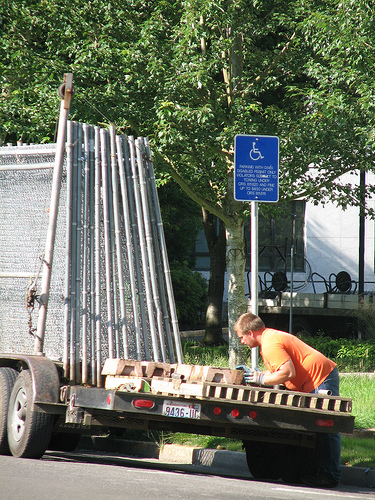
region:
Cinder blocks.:
[114, 331, 198, 399]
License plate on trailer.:
[156, 387, 248, 426]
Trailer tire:
[9, 375, 64, 454]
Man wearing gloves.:
[223, 293, 370, 413]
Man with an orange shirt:
[223, 290, 365, 413]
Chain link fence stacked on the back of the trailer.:
[40, 276, 150, 325]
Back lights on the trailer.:
[97, 380, 168, 428]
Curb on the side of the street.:
[184, 444, 239, 475]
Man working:
[218, 278, 348, 430]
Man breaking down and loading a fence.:
[159, 274, 311, 414]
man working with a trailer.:
[19, 55, 354, 450]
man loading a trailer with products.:
[36, 257, 344, 455]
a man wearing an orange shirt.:
[222, 297, 355, 464]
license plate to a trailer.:
[141, 394, 221, 442]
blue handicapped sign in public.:
[226, 120, 287, 224]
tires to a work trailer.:
[1, 361, 61, 468]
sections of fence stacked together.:
[6, 73, 183, 360]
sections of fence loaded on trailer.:
[0, 180, 353, 418]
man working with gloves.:
[235, 310, 296, 389]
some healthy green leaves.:
[99, 21, 331, 119]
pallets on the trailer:
[76, 361, 351, 430]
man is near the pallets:
[103, 369, 351, 415]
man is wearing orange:
[258, 328, 338, 390]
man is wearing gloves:
[235, 364, 269, 388]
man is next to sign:
[228, 129, 346, 411]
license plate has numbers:
[160, 399, 201, 418]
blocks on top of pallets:
[105, 356, 243, 394]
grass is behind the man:
[182, 335, 374, 463]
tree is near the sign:
[0, 1, 374, 307]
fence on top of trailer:
[1, 73, 189, 385]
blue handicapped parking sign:
[226, 125, 286, 215]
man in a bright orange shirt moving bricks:
[231, 308, 348, 396]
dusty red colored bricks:
[100, 354, 244, 388]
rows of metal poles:
[57, 114, 187, 359]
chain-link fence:
[0, 139, 64, 358]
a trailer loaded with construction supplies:
[0, 350, 353, 486]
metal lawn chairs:
[261, 262, 357, 298]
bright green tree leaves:
[0, 0, 374, 132]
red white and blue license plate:
[161, 399, 202, 423]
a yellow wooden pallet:
[150, 375, 357, 417]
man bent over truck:
[234, 308, 352, 493]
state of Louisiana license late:
[159, 392, 206, 427]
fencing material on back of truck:
[4, 110, 188, 399]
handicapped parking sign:
[225, 123, 278, 405]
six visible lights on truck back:
[77, 392, 372, 439]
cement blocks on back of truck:
[101, 349, 360, 422]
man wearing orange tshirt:
[226, 310, 334, 390]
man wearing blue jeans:
[289, 353, 351, 489]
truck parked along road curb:
[4, 364, 321, 494]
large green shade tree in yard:
[23, 23, 353, 355]